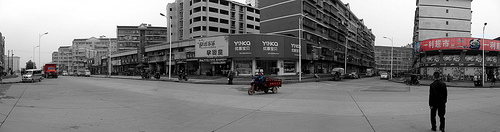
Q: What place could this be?
A: It is a street.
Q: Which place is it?
A: It is a street.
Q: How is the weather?
A: It is cloudy.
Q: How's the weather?
A: It is cloudy.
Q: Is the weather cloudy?
A: Yes, it is cloudy.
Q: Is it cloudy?
A: Yes, it is cloudy.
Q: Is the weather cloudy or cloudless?
A: It is cloudy.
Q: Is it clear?
A: No, it is cloudy.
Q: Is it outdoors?
A: Yes, it is outdoors.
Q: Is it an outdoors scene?
A: Yes, it is outdoors.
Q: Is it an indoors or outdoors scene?
A: It is outdoors.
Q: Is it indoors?
A: No, it is outdoors.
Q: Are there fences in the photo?
A: No, there are no fences.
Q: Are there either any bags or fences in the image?
A: No, there are no fences or bags.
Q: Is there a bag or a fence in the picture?
A: No, there are no fences or bags.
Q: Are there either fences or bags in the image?
A: No, there are no fences or bags.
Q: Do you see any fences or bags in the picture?
A: No, there are no fences or bags.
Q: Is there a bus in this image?
A: No, there are no buses.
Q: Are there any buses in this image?
A: No, there are no buses.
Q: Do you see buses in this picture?
A: No, there are no buses.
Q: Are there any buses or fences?
A: No, there are no buses or fences.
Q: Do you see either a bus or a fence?
A: No, there are no buses or fences.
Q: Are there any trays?
A: No, there are no trays.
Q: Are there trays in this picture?
A: No, there are no trays.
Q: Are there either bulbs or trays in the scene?
A: No, there are no trays or bulbs.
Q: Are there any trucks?
A: Yes, there is a truck.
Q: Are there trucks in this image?
A: Yes, there is a truck.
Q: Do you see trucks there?
A: Yes, there is a truck.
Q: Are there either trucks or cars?
A: Yes, there is a truck.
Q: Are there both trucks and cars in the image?
A: Yes, there are both a truck and a car.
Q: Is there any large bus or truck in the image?
A: Yes, there is a large truck.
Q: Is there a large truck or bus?
A: Yes, there is a large truck.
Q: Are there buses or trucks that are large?
A: Yes, the truck is large.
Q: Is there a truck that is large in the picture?
A: Yes, there is a large truck.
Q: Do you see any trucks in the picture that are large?
A: Yes, there is a truck that is large.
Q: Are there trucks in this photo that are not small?
A: Yes, there is a large truck.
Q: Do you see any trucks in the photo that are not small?
A: Yes, there is a large truck.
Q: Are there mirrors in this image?
A: No, there are no mirrors.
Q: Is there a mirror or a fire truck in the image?
A: No, there are no mirrors or fire trucks.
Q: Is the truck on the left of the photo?
A: Yes, the truck is on the left of the image.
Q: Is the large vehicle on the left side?
A: Yes, the truck is on the left of the image.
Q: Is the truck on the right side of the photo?
A: No, the truck is on the left of the image.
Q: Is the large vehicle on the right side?
A: No, the truck is on the left of the image.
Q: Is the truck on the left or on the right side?
A: The truck is on the left of the image.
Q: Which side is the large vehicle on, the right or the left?
A: The truck is on the left of the image.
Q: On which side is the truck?
A: The truck is on the left of the image.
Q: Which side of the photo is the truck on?
A: The truck is on the left of the image.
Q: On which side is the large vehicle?
A: The truck is on the left of the image.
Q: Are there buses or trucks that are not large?
A: No, there is a truck but it is large.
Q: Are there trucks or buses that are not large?
A: No, there is a truck but it is large.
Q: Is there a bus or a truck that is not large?
A: No, there is a truck but it is large.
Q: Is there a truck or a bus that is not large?
A: No, there is a truck but it is large.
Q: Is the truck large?
A: Yes, the truck is large.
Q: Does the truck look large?
A: Yes, the truck is large.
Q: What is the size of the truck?
A: The truck is large.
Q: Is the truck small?
A: No, the truck is large.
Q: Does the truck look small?
A: No, the truck is large.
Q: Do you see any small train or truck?
A: No, there is a truck but it is large.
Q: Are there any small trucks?
A: No, there is a truck but it is large.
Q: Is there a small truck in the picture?
A: No, there is a truck but it is large.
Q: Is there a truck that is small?
A: No, there is a truck but it is large.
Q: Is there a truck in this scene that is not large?
A: No, there is a truck but it is large.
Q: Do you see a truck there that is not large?
A: No, there is a truck but it is large.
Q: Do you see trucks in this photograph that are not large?
A: No, there is a truck but it is large.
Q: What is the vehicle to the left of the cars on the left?
A: The vehicle is a truck.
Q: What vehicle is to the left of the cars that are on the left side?
A: The vehicle is a truck.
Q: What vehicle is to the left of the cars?
A: The vehicle is a truck.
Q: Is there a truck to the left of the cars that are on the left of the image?
A: Yes, there is a truck to the left of the cars.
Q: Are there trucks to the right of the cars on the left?
A: No, the truck is to the left of the cars.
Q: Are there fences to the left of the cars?
A: No, there is a truck to the left of the cars.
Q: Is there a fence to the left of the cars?
A: No, there is a truck to the left of the cars.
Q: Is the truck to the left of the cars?
A: Yes, the truck is to the left of the cars.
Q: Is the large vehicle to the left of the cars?
A: Yes, the truck is to the left of the cars.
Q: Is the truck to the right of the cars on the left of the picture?
A: No, the truck is to the left of the cars.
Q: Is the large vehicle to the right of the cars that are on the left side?
A: No, the truck is to the left of the cars.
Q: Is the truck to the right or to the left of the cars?
A: The truck is to the left of the cars.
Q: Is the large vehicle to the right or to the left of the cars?
A: The truck is to the left of the cars.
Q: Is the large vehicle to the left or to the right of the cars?
A: The truck is to the left of the cars.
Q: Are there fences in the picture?
A: No, there are no fences.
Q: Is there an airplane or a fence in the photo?
A: No, there are no fences or airplanes.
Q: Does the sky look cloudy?
A: Yes, the sky is cloudy.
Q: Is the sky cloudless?
A: No, the sky is cloudy.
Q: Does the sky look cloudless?
A: No, the sky is cloudy.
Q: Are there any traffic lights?
A: No, there are no traffic lights.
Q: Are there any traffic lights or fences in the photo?
A: No, there are no traffic lights or fences.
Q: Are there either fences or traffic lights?
A: No, there are no traffic lights or fences.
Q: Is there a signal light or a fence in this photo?
A: No, there are no traffic lights or fences.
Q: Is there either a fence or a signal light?
A: No, there are no traffic lights or fences.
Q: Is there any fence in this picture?
A: No, there are no fences.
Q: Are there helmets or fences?
A: No, there are no fences or helmets.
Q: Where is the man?
A: The man is on the street.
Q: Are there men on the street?
A: Yes, there is a man on the street.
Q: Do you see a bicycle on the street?
A: No, there is a man on the street.